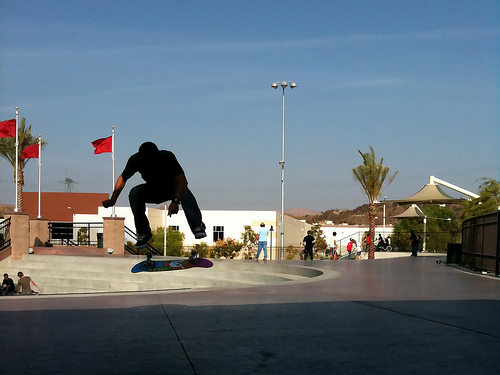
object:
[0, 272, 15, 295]
person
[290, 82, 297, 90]
light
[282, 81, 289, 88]
light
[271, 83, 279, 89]
light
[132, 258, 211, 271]
skateboard bottom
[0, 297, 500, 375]
shadow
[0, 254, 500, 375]
cement surface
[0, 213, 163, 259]
fence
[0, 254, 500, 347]
road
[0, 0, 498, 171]
sky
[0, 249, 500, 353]
platform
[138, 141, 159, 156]
head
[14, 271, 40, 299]
people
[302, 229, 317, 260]
people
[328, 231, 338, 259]
people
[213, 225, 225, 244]
window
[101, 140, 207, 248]
airborne man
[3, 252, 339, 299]
concrete stairs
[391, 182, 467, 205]
umbrella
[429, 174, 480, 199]
pole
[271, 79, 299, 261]
lamp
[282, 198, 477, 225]
mountains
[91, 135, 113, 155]
flag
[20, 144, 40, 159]
flag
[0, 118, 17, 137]
flag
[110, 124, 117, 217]
pole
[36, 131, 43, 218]
pole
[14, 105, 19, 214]
pole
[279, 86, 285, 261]
pole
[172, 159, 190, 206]
arm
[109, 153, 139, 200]
arm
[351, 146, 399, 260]
palm tree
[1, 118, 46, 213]
palm tree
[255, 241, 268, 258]
jeans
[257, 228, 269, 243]
shirt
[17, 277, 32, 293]
brown shirt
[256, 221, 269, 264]
man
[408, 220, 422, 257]
people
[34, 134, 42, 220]
flagpole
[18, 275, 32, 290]
shirt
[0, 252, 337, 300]
steps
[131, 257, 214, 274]
skateboard